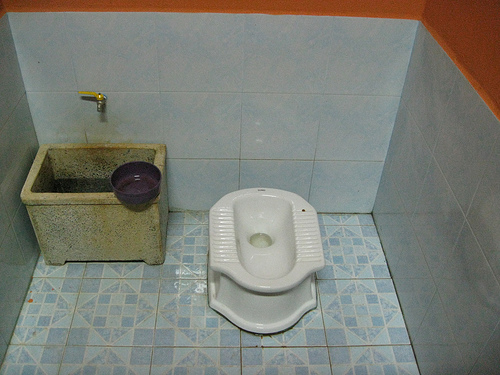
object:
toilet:
[208, 187, 325, 334]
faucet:
[78, 91, 106, 113]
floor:
[0, 280, 173, 374]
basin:
[20, 141, 168, 265]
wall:
[228, 38, 285, 92]